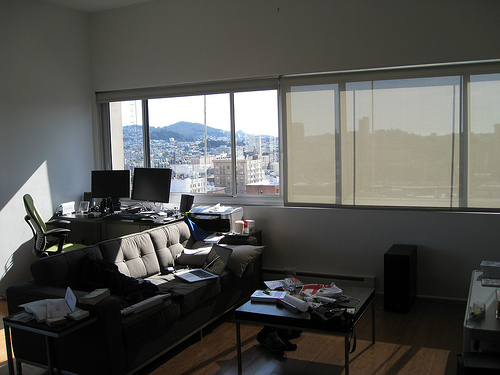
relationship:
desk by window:
[55, 201, 248, 246] [91, 55, 499, 216]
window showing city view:
[91, 55, 499, 216] [117, 103, 282, 199]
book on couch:
[78, 284, 113, 307] [4, 217, 265, 374]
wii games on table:
[477, 256, 500, 287] [464, 266, 500, 357]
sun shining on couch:
[113, 216, 224, 288] [4, 217, 265, 374]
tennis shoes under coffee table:
[257, 323, 306, 353] [231, 274, 379, 374]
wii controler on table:
[302, 294, 340, 304] [232, 274, 379, 375]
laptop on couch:
[172, 241, 235, 284] [4, 217, 265, 374]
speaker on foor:
[382, 242, 419, 314] [377, 293, 465, 316]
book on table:
[250, 288, 290, 304] [232, 274, 379, 375]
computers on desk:
[89, 167, 175, 221] [55, 201, 248, 246]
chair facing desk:
[22, 193, 89, 259] [55, 201, 248, 246]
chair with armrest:
[22, 193, 89, 259] [41, 217, 72, 240]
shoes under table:
[257, 323, 306, 353] [232, 274, 379, 375]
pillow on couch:
[176, 240, 270, 279] [4, 217, 265, 374]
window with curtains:
[91, 55, 499, 216] [280, 57, 498, 215]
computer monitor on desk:
[91, 168, 132, 203] [55, 201, 248, 246]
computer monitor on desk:
[130, 163, 175, 207] [55, 201, 248, 246]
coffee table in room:
[231, 274, 379, 374] [0, 0, 499, 374]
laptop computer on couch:
[172, 241, 235, 284] [4, 217, 265, 374]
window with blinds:
[91, 55, 499, 216] [280, 57, 498, 215]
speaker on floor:
[382, 242, 419, 314] [0, 290, 469, 375]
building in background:
[171, 132, 278, 197] [117, 103, 282, 199]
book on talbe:
[250, 288, 290, 304] [231, 274, 379, 374]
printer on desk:
[183, 201, 245, 236] [55, 201, 248, 246]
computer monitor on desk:
[131, 168, 173, 203] [55, 201, 248, 246]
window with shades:
[91, 55, 499, 216] [280, 57, 498, 215]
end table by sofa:
[1, 301, 101, 375] [4, 217, 265, 374]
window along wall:
[91, 55, 499, 216] [85, 1, 499, 277]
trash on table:
[263, 273, 325, 295] [232, 274, 379, 375]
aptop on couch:
[172, 241, 235, 284] [4, 217, 265, 374]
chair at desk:
[22, 193, 89, 259] [55, 201, 248, 246]